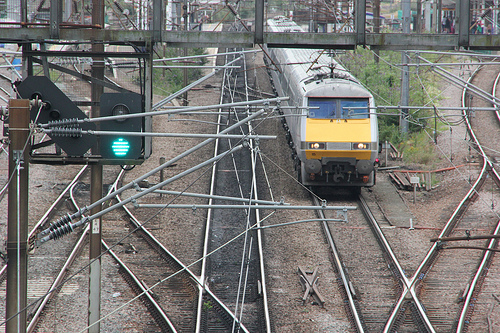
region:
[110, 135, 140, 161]
Green traffic light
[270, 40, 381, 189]
Silver and yellow train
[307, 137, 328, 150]
Front right light of train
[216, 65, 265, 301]
Adjacent train track is metal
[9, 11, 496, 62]
Metal bar above tracks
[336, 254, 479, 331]
Crossing tracks in front of train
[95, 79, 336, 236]
Electrical system for powering train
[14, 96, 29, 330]
Brown telephone pole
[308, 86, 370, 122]
Clear windshield of train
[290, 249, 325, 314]
Metal X between tracks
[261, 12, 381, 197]
yellow and silver train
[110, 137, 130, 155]
green light is lit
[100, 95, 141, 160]
small stop light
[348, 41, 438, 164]
green grass beside train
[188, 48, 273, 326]
straight train tracks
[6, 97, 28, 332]
wood pole beside light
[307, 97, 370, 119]
window on front of train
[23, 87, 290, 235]
metal poles in front of light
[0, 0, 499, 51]
gray metal grate overhead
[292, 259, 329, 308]
metal X in between train tracks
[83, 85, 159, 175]
a traffic light over the rails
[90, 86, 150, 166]
traffic ligh is green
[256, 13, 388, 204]
train is passing over the rails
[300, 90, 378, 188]
front of train is yellow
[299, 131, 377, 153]
headlights of train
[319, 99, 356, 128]
black wipes on windshield of train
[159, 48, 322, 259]
metal stick next to traffic light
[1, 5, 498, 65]
metal structure over the rails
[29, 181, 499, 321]
five lines of rails on ground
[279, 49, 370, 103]
roof of train is gray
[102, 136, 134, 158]
green traffic signal light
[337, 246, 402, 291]
silver metal train tracks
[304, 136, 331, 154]
light on front of train engine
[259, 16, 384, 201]
silver and yellow train engine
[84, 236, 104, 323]
brown and silver metal pole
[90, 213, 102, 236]
white sticker on side of metal pole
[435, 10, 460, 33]
group of people standing in line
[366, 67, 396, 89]
bushes growing beside train tracks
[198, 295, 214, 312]
small grass growing on train tracks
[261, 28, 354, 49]
grey metal framing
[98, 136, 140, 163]
green signal light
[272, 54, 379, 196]
yellow and gray passenger train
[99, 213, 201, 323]
gray tracks at train connector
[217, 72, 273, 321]
gray tracks at train connector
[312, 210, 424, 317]
gray tracks at train connector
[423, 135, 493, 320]
gray tracks at train connector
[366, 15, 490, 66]
gray support at train connector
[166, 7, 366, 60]
gray support at train connector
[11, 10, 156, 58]
gray support at train connector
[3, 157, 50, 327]
gray support at train connector